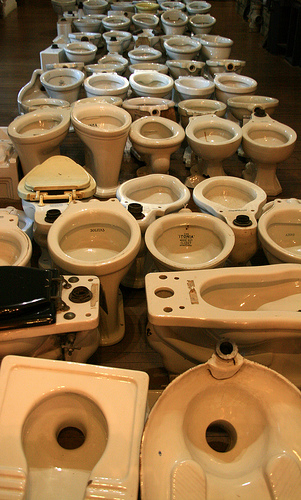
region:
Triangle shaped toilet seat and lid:
[13, 156, 98, 199]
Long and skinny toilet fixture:
[145, 262, 299, 347]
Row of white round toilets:
[84, 69, 256, 95]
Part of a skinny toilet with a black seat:
[2, 260, 100, 354]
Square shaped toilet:
[1, 356, 137, 498]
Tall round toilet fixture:
[45, 201, 143, 346]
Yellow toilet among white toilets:
[133, 1, 160, 14]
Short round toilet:
[96, 37, 127, 73]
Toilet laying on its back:
[16, 69, 55, 117]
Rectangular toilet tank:
[38, 38, 65, 71]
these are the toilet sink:
[39, 7, 218, 159]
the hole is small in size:
[192, 408, 264, 462]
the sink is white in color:
[210, 440, 288, 498]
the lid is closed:
[34, 157, 79, 189]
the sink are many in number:
[88, 12, 210, 134]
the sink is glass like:
[205, 261, 269, 315]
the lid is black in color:
[9, 269, 43, 308]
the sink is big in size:
[81, 108, 133, 167]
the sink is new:
[221, 280, 277, 321]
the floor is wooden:
[12, 27, 30, 57]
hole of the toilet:
[194, 410, 239, 454]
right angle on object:
[115, 355, 163, 406]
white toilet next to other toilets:
[135, 116, 180, 149]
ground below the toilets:
[125, 324, 147, 358]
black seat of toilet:
[0, 267, 58, 311]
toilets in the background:
[62, 1, 212, 36]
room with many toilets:
[33, 11, 245, 171]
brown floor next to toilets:
[7, 16, 40, 46]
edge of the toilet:
[130, 230, 143, 252]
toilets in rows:
[53, 9, 214, 131]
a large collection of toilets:
[0, 0, 300, 497]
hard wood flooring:
[2, 4, 74, 113]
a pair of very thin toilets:
[4, 266, 299, 335]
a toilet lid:
[26, 153, 88, 188]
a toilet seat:
[22, 157, 104, 201]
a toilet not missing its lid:
[13, 160, 99, 245]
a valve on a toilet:
[47, 332, 92, 357]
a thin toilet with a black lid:
[0, 255, 97, 355]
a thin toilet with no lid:
[145, 261, 300, 347]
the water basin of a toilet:
[34, 39, 74, 69]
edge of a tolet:
[154, 136, 172, 147]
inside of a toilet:
[53, 421, 86, 461]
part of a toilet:
[151, 468, 165, 489]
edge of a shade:
[216, 447, 240, 468]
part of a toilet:
[143, 452, 176, 485]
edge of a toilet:
[135, 402, 159, 441]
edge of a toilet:
[127, 420, 154, 473]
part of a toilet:
[93, 439, 113, 464]